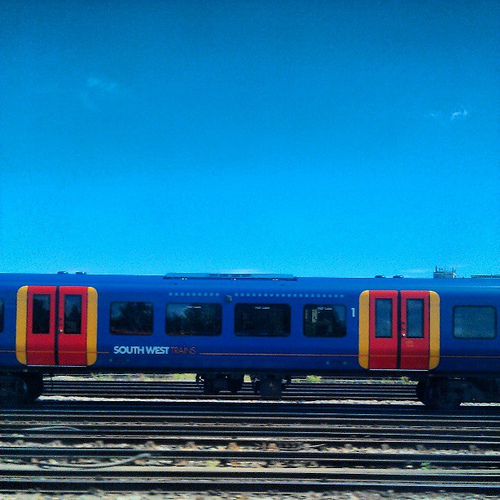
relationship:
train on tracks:
[2, 266, 498, 408] [6, 378, 499, 499]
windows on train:
[15, 288, 498, 340] [2, 266, 498, 408]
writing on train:
[110, 343, 211, 359] [2, 266, 498, 408]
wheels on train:
[3, 366, 499, 415] [2, 266, 498, 408]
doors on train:
[13, 281, 111, 365] [2, 266, 498, 408]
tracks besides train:
[6, 378, 499, 499] [2, 266, 498, 408]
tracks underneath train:
[6, 378, 499, 499] [2, 266, 498, 408]